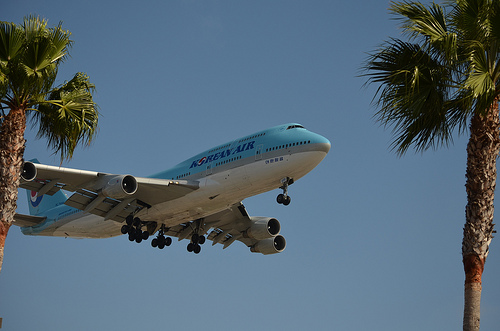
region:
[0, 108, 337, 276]
airplane in the sky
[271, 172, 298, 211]
front wheels of an airplane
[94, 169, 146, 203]
engine on an airplane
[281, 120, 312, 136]
cockpit windows on an airplane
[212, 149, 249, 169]
side windows on an airplane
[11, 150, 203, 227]
wind on an airplane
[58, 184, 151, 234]
flaps on the wing of an airplane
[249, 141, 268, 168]
door on an airplane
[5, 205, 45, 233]
tail wing of an airplane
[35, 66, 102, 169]
green leaves on a palm tree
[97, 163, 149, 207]
Large metal airplane engine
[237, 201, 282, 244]
Large metal airplane engine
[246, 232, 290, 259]
Large metal airplane engine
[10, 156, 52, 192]
Large metal airplane engine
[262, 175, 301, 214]
Rubber airplane wheels and landing gear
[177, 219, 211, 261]
Rubber airplane wheels and landing gear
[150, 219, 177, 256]
Rubber airplane wheels and landing gear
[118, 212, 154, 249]
Rubber airplane wheels and landing gear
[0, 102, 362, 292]
Large blue and white airplane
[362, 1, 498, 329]
Large palm tree with green fronds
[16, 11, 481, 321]
a plane flying low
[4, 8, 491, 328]
a plane coming in for landing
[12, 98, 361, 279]
a large commercial plane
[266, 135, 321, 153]
a row of plane windows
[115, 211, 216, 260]
a plane's landing gear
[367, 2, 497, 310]
a large palm tree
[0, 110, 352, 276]
a blue and white aircraft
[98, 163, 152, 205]
a plane engine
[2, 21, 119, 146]
green palm leaves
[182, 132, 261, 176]
an air lines logo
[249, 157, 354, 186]
The bottom of the plane is white.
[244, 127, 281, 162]
The top of the plane is blue.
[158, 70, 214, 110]
The sky is blue.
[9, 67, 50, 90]
The leaves on the palm trees are green.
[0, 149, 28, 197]
The palm tree's trunk is brown.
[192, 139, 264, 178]
Words written on the plane.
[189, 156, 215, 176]
The "O" resembles the Pepsi sign.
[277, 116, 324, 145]
The cockpit where the pilot sits.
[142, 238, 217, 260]
The wheels are down.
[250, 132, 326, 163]
Windows for the passengers to look out.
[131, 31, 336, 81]
clear blue skies overhead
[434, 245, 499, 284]
red spot on palm tree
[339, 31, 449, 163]
green pines on palm tree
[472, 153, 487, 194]
brown bark on tree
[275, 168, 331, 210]
black front wheel on airplane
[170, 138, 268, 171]
blue words on side of plane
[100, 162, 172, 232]
silver engine on plane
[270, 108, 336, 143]
front window of blue airplane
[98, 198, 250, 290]
cluster of rear engines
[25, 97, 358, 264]
large blue and silver airplane in the air